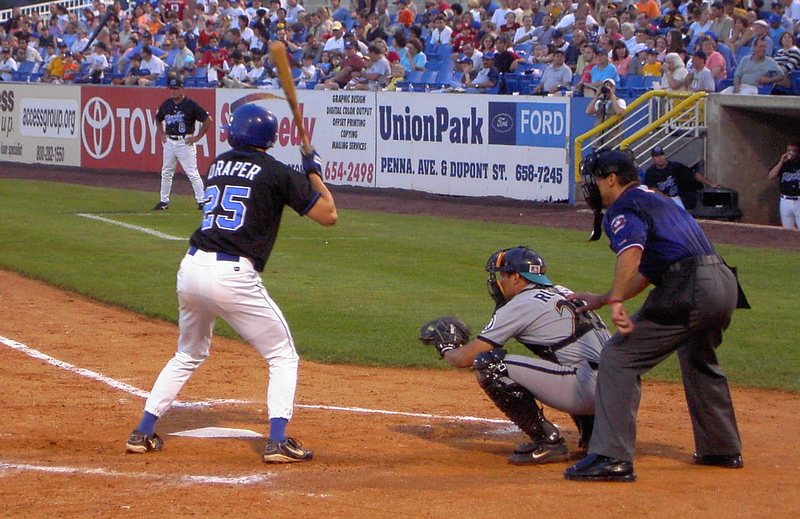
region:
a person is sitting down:
[422, 13, 449, 37]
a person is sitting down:
[461, 26, 473, 43]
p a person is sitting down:
[491, 7, 540, 41]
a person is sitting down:
[561, 10, 585, 32]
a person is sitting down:
[587, 18, 620, 56]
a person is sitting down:
[624, 26, 646, 59]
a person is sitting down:
[583, 52, 623, 81]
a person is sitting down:
[543, 45, 571, 97]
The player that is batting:
[118, 34, 337, 476]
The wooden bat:
[264, 35, 334, 155]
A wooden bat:
[266, 34, 336, 179]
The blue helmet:
[214, 90, 280, 147]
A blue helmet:
[212, 92, 288, 149]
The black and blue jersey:
[174, 143, 302, 237]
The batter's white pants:
[146, 245, 328, 409]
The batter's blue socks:
[134, 407, 310, 434]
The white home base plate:
[172, 417, 263, 447]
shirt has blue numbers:
[205, 183, 254, 245]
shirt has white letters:
[205, 156, 264, 184]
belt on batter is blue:
[184, 240, 257, 264]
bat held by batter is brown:
[260, 31, 329, 159]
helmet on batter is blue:
[216, 99, 296, 163]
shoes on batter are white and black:
[120, 419, 180, 462]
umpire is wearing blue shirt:
[600, 185, 728, 275]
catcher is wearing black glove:
[421, 309, 478, 368]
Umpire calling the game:
[565, 152, 746, 481]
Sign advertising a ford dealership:
[377, 91, 577, 201]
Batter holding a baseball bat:
[128, 43, 314, 461]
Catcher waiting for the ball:
[420, 244, 617, 462]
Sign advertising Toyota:
[83, 86, 214, 179]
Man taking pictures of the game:
[586, 79, 624, 242]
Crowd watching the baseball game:
[1, 3, 798, 97]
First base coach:
[150, 76, 222, 216]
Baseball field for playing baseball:
[2, 164, 798, 517]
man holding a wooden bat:
[131, 35, 337, 463]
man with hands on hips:
[145, 78, 212, 211]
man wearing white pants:
[116, 105, 343, 467]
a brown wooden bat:
[268, 35, 313, 145]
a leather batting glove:
[299, 151, 320, 176]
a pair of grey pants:
[584, 262, 741, 459]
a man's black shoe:
[563, 455, 633, 480]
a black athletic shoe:
[507, 437, 568, 466]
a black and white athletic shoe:
[265, 437, 313, 463]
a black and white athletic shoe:
[124, 432, 162, 453]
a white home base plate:
[164, 425, 263, 439]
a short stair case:
[569, 93, 701, 205]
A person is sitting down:
[461, 49, 502, 93]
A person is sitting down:
[354, 43, 397, 96]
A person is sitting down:
[396, 35, 429, 70]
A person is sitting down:
[666, 30, 684, 54]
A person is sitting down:
[677, 52, 712, 98]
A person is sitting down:
[719, 41, 770, 91]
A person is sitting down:
[297, 28, 329, 53]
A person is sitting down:
[201, 29, 233, 63]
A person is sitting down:
[166, 34, 201, 66]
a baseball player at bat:
[124, 41, 341, 463]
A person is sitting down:
[540, 52, 576, 93]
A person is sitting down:
[461, 36, 485, 58]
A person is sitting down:
[366, 46, 386, 74]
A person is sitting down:
[376, 49, 409, 86]